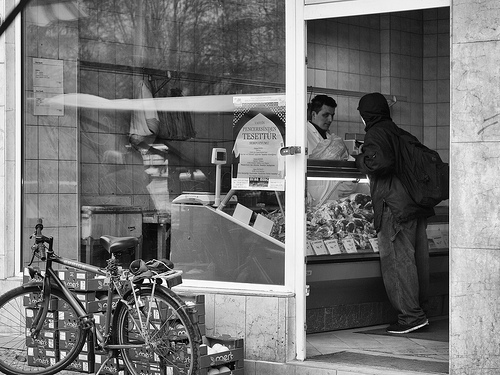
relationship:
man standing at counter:
[357, 89, 448, 334] [168, 158, 452, 334]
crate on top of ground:
[26, 345, 61, 367] [2, 344, 499, 373]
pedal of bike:
[73, 314, 100, 332] [1, 218, 199, 374]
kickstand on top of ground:
[94, 353, 114, 375] [2, 344, 499, 373]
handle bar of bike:
[36, 242, 48, 262] [1, 218, 199, 374]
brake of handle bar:
[29, 243, 41, 265] [36, 242, 48, 262]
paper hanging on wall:
[33, 55, 66, 118] [22, 0, 450, 278]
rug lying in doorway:
[305, 349, 447, 373] [306, 7, 448, 374]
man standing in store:
[357, 89, 448, 334] [24, 0, 447, 374]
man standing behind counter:
[305, 93, 352, 161] [168, 158, 452, 334]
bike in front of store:
[1, 218, 199, 374] [24, 0, 447, 374]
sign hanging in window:
[231, 94, 288, 191] [24, 0, 285, 284]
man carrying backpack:
[357, 89, 448, 334] [379, 120, 452, 206]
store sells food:
[24, 0, 447, 374] [274, 193, 382, 255]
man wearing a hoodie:
[357, 89, 448, 334] [352, 90, 436, 232]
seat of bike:
[98, 234, 139, 253] [1, 218, 199, 374]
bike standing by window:
[1, 218, 199, 374] [24, 0, 285, 284]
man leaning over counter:
[357, 89, 448, 334] [168, 158, 452, 334]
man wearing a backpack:
[357, 89, 448, 334] [379, 120, 452, 206]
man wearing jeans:
[357, 89, 448, 334] [374, 203, 430, 335]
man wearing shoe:
[357, 89, 448, 334] [386, 309, 430, 335]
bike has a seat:
[1, 218, 199, 374] [98, 234, 139, 253]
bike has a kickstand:
[1, 218, 199, 374] [94, 353, 114, 375]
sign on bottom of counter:
[341, 235, 360, 254] [168, 158, 452, 334]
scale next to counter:
[170, 145, 241, 207] [168, 158, 452, 334]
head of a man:
[356, 93, 392, 125] [357, 89, 448, 334]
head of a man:
[309, 94, 338, 132] [305, 93, 352, 161]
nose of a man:
[327, 113, 334, 123] [305, 93, 352, 161]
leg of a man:
[415, 205, 429, 318] [357, 89, 448, 334]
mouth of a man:
[321, 123, 332, 128] [305, 93, 352, 161]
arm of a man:
[351, 129, 393, 174] [357, 89, 448, 334]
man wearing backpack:
[357, 89, 448, 334] [379, 120, 452, 206]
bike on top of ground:
[1, 218, 199, 374] [2, 344, 499, 373]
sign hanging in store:
[341, 235, 360, 254] [24, 0, 447, 374]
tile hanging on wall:
[97, 71, 117, 100] [22, 0, 450, 278]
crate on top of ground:
[60, 348, 93, 373] [2, 344, 499, 373]